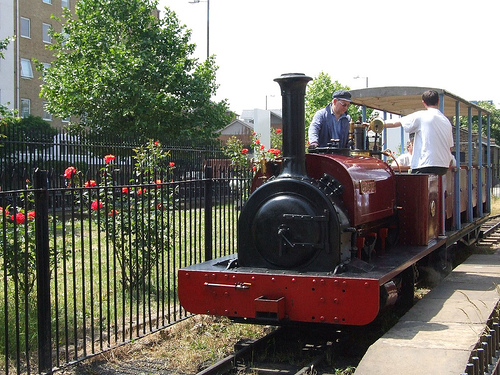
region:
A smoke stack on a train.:
[253, 43, 324, 168]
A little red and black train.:
[179, 37, 487, 354]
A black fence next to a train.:
[7, 150, 256, 349]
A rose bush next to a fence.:
[55, 132, 179, 302]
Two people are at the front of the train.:
[313, 81, 450, 196]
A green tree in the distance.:
[66, 7, 202, 136]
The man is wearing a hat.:
[327, 82, 357, 115]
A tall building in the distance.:
[8, 0, 184, 151]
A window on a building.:
[17, 15, 34, 47]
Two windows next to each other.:
[13, 12, 57, 49]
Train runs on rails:
[163, 56, 498, 333]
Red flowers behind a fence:
[53, 136, 183, 293]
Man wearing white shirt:
[371, 84, 460, 183]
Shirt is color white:
[394, 106, 458, 171]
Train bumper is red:
[162, 263, 384, 342]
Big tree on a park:
[43, 1, 233, 167]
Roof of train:
[345, 76, 493, 121]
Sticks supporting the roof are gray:
[438, 93, 499, 229]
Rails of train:
[203, 331, 341, 373]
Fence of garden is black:
[1, 153, 234, 361]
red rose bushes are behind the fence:
[1, 125, 291, 306]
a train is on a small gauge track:
[178, 66, 494, 363]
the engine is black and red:
[178, 71, 440, 324]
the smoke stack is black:
[270, 70, 312, 182]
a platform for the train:
[353, 245, 499, 373]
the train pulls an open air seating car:
[339, 84, 499, 235]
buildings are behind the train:
[8, 4, 498, 218]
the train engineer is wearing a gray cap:
[308, 88, 355, 157]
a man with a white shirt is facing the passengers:
[378, 90, 450, 175]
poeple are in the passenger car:
[389, 137, 465, 204]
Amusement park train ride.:
[185, 71, 497, 313]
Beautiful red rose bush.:
[58, 151, 185, 280]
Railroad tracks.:
[182, 333, 322, 374]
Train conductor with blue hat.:
[308, 87, 353, 168]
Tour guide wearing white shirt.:
[408, 91, 463, 175]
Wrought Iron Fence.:
[35, 160, 220, 332]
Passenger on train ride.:
[402, 134, 413, 167]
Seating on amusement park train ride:
[457, 114, 497, 224]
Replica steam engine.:
[236, 71, 408, 301]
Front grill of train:
[165, 259, 410, 325]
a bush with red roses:
[61, 142, 192, 282]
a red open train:
[200, 86, 490, 316]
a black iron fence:
[4, 154, 291, 373]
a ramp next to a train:
[358, 243, 499, 366]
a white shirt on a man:
[397, 90, 456, 168]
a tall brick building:
[5, 1, 116, 145]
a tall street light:
[188, 0, 222, 108]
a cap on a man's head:
[332, 88, 356, 105]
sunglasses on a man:
[338, 99, 352, 109]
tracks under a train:
[194, 323, 354, 371]